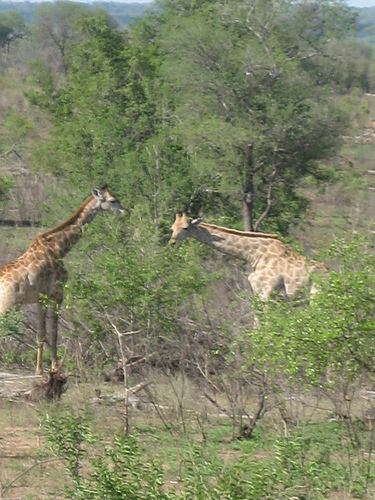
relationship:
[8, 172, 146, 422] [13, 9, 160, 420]
adult giraffe to left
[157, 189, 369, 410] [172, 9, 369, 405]
adult giraffe to right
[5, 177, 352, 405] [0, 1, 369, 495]
two giraffes are in jungle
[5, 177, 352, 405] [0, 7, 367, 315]
two giraffes are among trees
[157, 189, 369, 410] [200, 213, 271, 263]
adult giraffe has bent neck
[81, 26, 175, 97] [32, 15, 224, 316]
green leaves are on tree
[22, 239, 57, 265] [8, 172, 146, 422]
brown spots are on adult giraffe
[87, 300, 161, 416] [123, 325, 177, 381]
branches have no leaves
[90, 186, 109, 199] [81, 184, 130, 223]
ear on side of head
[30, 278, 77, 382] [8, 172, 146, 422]
two front legs are on adult giraffe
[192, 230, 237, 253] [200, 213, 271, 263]
shadow on bent neck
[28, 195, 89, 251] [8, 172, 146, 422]
fur on adult giraffe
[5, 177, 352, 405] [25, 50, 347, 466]
two giraffes are in plains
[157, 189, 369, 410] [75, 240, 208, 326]
adult giraffe eating brush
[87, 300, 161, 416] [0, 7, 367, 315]
branches are from trees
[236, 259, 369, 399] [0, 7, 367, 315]
leaves are on trees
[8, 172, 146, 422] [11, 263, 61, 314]
adult giraffe has stomach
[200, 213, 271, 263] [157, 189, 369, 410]
bent neck from adult giraffe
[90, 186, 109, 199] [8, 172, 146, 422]
ear of adult giraffe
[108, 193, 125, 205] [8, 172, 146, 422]
eye of adult giraffe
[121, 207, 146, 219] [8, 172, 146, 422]
nose of adult giraffe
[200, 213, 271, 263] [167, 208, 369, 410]
mane on adult giraffe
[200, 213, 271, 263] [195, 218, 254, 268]
mane on bent neck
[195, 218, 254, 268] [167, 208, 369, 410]
bent neck on adult giraffe